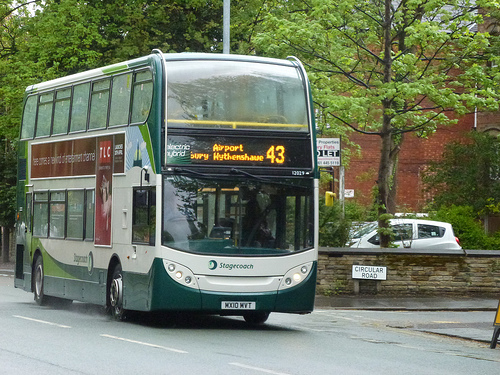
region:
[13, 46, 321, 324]
a double decker bus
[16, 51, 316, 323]
a green double decker bus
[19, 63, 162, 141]
windows on a double decker bus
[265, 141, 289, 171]
the number 43 on a bus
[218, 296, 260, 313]
a license plate on a bus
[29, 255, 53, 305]
the back tire on a bus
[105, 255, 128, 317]
the front tire on a bus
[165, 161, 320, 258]
the windshield on a double decker bus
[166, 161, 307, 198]
wiper blades on a bus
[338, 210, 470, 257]
a parked car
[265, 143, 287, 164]
The orange number 43.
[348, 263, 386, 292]
A sign that says CIRCULAR ROAD.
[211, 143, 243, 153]
The word Airport on a bus in orange LED's.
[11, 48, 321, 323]
A mostly green and white double decker bus.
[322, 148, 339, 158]
White letters that say LET on black background.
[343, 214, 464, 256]
A white parked vehicle behind the wall.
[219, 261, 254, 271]
Stagecoach in green letters on the bottom front of the bus.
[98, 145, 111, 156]
White TLC on the side of the bus.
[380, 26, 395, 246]
Brown tree trunk in front of a white car behind a wall.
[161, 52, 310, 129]
the top front windshield of a double decker bus.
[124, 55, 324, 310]
large two story bus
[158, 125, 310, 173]
electronic sign on front of bus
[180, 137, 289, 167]
orange lettering on sign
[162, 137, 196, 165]
green sign in corner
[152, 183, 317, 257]
front window of bus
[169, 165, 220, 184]
black window wiper on bus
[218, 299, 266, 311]
licence plate on bus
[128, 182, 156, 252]
side window on bus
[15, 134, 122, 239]
red sign on side of bus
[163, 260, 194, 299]
front lights of bus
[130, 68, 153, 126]
Small window on a bus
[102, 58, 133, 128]
Small window on a bus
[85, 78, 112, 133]
Small window on a bus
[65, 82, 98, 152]
Small window on a bus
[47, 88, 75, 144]
Small window on a bus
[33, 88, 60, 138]
Small window on a bus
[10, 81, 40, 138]
Small window on a bus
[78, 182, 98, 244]
Small window on a bus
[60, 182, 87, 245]
Small window on a bus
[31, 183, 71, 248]
Small window on a bus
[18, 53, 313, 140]
top level of a bus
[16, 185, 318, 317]
bottom level of a bus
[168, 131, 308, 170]
digital display on bus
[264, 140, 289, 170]
route number on display of bus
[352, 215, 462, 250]
small silver car behind wall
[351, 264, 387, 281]
small white sign in front of wall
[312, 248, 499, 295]
a small stone wall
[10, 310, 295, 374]
white traffic lines on road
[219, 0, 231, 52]
a metal pole behind bus